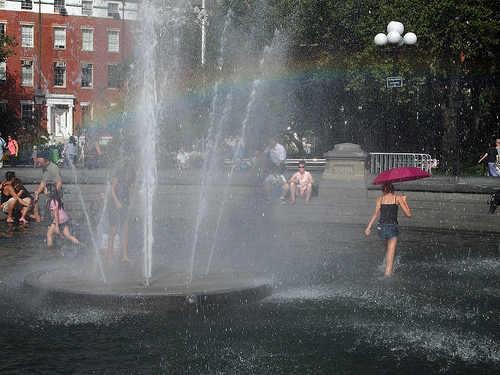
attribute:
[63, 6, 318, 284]
water — shooting upward, spraying, in a stream, large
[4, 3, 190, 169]
building — brick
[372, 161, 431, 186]
umbrella — red, large, pink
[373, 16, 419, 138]
light — white, tall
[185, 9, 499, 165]
trees — large, green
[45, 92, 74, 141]
entry way — white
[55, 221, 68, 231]
shorts — dark, denim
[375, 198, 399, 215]
tank top — black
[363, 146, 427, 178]
fence — gray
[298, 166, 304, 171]
sunglasses — dark, black